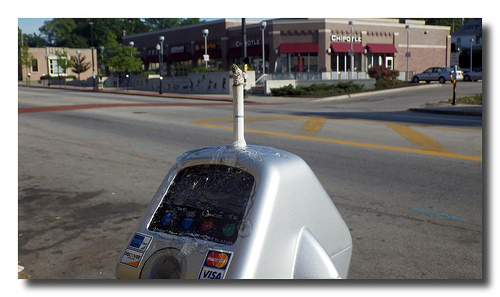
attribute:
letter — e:
[357, 35, 362, 41]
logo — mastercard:
[199, 245, 230, 260]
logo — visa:
[191, 255, 222, 284]